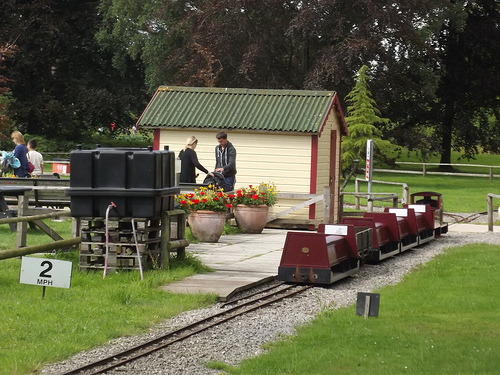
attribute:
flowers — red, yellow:
[176, 172, 227, 211]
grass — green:
[206, 240, 498, 372]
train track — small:
[60, 280, 314, 372]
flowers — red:
[224, 189, 264, 205]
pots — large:
[187, 207, 268, 242]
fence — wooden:
[339, 132, 488, 207]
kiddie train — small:
[278, 181, 451, 289]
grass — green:
[373, 267, 495, 369]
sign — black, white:
[11, 225, 111, 313]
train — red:
[282, 181, 444, 281]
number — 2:
[21, 226, 82, 281]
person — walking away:
[19, 141, 45, 219]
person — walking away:
[0, 122, 27, 209]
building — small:
[133, 86, 348, 222]